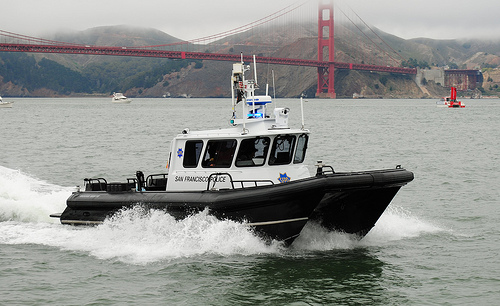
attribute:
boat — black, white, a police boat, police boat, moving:
[51, 50, 415, 248]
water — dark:
[0, 95, 500, 303]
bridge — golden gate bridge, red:
[0, 0, 422, 98]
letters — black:
[173, 176, 225, 182]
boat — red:
[445, 88, 466, 108]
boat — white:
[110, 92, 132, 104]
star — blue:
[278, 171, 293, 184]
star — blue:
[177, 149, 185, 157]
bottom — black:
[51, 170, 414, 251]